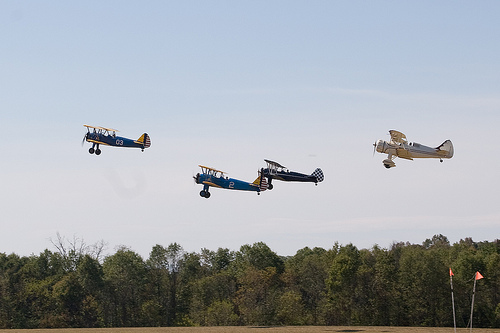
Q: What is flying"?
A: Planes.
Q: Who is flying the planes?
A: Pilots.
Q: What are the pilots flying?
A: Planes.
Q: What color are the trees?
A: Green.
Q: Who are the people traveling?
A: By plane.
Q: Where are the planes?
A: In the sky.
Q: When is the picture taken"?
A: Daytime.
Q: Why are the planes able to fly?
A: Aerodynamics.